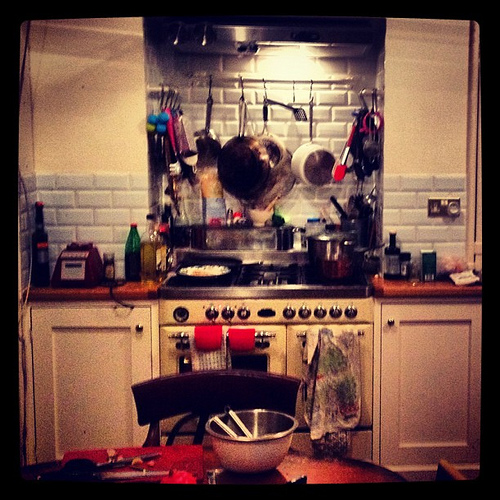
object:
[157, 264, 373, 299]
stove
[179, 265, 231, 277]
food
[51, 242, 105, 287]
appliance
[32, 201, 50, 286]
bottle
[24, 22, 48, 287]
corner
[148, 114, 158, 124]
item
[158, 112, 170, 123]
item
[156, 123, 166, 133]
item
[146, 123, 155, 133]
item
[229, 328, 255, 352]
towel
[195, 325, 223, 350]
towel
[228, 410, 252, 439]
spoon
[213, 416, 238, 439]
spoon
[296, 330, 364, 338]
handle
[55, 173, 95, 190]
tile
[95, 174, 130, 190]
tile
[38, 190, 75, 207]
tile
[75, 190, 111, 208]
tile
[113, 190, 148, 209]
tile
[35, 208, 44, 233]
neck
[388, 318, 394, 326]
handle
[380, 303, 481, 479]
closet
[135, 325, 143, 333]
handle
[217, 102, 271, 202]
artifact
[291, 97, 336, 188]
artifact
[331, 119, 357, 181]
artifact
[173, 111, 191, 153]
artifact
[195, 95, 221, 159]
artifact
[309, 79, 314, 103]
hook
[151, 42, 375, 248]
wall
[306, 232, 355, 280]
pot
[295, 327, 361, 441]
door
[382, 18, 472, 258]
wall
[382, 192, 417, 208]
subway tile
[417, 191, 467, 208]
subway tile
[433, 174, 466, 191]
subway tile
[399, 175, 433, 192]
subway tile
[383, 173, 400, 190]
subway tile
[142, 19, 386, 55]
vent hood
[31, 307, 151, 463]
cabinet door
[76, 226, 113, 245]
tile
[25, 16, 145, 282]
wall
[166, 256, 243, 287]
appliances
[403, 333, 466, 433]
paint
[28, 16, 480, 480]
image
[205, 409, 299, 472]
bowl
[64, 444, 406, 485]
table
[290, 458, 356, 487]
wood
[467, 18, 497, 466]
frame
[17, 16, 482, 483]
picture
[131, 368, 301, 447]
chair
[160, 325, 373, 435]
stove's door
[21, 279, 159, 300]
counter